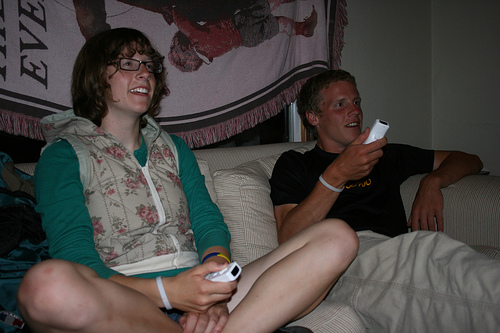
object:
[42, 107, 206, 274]
vest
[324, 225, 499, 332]
blanket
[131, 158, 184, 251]
zipper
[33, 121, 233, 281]
jacket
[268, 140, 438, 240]
black shirt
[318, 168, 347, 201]
whiteband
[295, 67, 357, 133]
hair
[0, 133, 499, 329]
couch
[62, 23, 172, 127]
hair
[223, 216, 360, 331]
leg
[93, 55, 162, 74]
eyeglasses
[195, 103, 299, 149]
window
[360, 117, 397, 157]
controller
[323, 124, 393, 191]
hand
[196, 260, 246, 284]
controller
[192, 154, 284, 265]
pillow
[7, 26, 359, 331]
girl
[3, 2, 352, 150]
blanket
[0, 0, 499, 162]
wall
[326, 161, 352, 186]
wrist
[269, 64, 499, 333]
boy